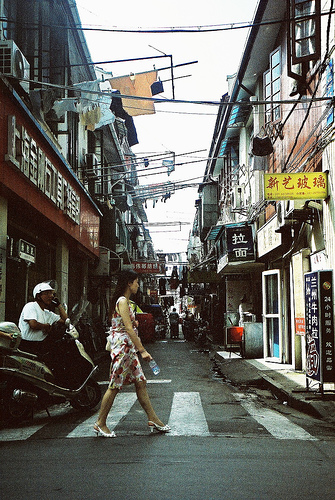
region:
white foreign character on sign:
[230, 232, 246, 246]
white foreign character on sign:
[231, 244, 251, 259]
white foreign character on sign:
[310, 275, 318, 287]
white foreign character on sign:
[310, 287, 317, 301]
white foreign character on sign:
[308, 301, 318, 313]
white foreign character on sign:
[309, 312, 318, 327]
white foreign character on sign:
[309, 326, 318, 339]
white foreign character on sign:
[323, 294, 331, 304]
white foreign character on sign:
[323, 303, 331, 312]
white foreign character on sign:
[322, 311, 331, 320]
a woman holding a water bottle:
[139, 348, 158, 381]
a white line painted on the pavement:
[161, 373, 210, 452]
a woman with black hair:
[104, 269, 139, 324]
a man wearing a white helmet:
[29, 277, 58, 309]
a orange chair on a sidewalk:
[225, 319, 247, 358]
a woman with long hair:
[112, 265, 139, 314]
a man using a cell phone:
[44, 286, 58, 309]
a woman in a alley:
[164, 305, 182, 340]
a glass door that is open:
[259, 265, 279, 360]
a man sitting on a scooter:
[12, 281, 89, 407]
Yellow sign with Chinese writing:
[260, 172, 327, 199]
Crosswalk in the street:
[98, 385, 308, 437]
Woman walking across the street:
[95, 270, 164, 441]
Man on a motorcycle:
[13, 275, 100, 408]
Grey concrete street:
[108, 436, 285, 494]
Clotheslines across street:
[79, 150, 213, 198]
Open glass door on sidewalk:
[254, 266, 285, 363]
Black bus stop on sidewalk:
[297, 268, 333, 396]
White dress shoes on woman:
[87, 417, 176, 441]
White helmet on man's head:
[27, 281, 53, 294]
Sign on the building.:
[232, 145, 326, 229]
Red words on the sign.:
[240, 147, 307, 206]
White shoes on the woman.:
[91, 379, 221, 450]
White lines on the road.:
[153, 362, 254, 487]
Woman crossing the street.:
[50, 248, 181, 447]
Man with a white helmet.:
[16, 272, 108, 397]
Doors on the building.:
[239, 260, 327, 440]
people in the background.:
[148, 268, 235, 355]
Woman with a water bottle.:
[100, 284, 167, 414]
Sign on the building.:
[232, 129, 328, 226]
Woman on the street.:
[69, 266, 217, 499]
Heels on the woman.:
[31, 394, 167, 452]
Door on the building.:
[240, 261, 326, 366]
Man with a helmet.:
[5, 274, 100, 392]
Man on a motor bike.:
[14, 271, 128, 458]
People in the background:
[127, 227, 216, 343]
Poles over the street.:
[95, 142, 200, 255]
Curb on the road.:
[190, 285, 314, 443]